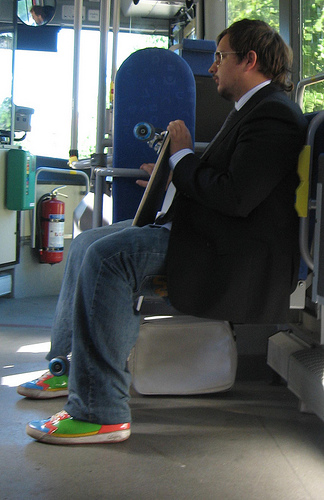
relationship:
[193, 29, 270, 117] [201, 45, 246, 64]
man wearing eyeglasses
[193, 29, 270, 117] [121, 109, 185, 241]
man with skateboard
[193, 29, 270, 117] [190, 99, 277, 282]
man wearing coat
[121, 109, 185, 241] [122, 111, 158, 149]
skateboard has wheels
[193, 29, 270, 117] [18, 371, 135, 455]
man wearing sneakers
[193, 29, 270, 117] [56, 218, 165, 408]
man wearing jeans